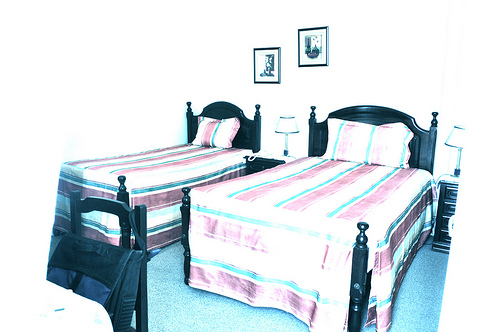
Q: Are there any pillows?
A: Yes, there is a pillow.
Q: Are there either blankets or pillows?
A: Yes, there is a pillow.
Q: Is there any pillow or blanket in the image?
A: Yes, there is a pillow.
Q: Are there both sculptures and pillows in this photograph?
A: No, there is a pillow but no sculptures.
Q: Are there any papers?
A: No, there are no papers.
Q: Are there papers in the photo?
A: No, there are no papers.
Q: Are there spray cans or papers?
A: No, there are no papers or spray cans.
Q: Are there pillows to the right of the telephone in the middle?
A: Yes, there is a pillow to the right of the phone.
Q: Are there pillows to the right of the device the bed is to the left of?
A: Yes, there is a pillow to the right of the phone.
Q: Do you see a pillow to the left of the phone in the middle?
A: No, the pillow is to the right of the telephone.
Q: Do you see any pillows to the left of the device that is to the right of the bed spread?
A: No, the pillow is to the right of the telephone.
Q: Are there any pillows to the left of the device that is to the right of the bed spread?
A: No, the pillow is to the right of the telephone.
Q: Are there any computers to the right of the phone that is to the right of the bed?
A: No, there is a pillow to the right of the phone.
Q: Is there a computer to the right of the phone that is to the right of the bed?
A: No, there is a pillow to the right of the phone.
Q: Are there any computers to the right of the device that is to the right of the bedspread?
A: No, there is a pillow to the right of the phone.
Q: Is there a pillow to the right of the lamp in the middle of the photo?
A: Yes, there is a pillow to the right of the lamp.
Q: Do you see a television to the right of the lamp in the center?
A: No, there is a pillow to the right of the lamp.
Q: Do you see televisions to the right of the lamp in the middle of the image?
A: No, there is a pillow to the right of the lamp.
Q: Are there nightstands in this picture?
A: Yes, there is a nightstand.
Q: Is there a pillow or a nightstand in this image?
A: Yes, there is a nightstand.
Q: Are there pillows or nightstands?
A: Yes, there is a nightstand.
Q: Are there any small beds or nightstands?
A: Yes, there is a small nightstand.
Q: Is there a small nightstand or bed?
A: Yes, there is a small nightstand.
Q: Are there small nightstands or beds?
A: Yes, there is a small nightstand.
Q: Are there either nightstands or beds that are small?
A: Yes, the nightstand is small.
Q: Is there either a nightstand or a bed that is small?
A: Yes, the nightstand is small.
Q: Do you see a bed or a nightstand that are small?
A: Yes, the nightstand is small.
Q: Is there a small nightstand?
A: Yes, there is a small nightstand.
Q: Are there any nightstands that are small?
A: Yes, there is a nightstand that is small.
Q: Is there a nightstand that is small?
A: Yes, there is a nightstand that is small.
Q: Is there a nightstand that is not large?
A: Yes, there is a small nightstand.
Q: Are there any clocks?
A: No, there are no clocks.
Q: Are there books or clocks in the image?
A: No, there are no clocks or books.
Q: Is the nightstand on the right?
A: Yes, the nightstand is on the right of the image.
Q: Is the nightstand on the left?
A: No, the nightstand is on the right of the image.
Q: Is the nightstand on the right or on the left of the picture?
A: The nightstand is on the right of the image.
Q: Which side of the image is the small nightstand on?
A: The nightstand is on the right of the image.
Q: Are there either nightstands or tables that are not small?
A: No, there is a nightstand but it is small.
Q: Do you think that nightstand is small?
A: Yes, the nightstand is small.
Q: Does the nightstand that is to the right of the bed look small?
A: Yes, the nightstand is small.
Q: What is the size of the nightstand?
A: The nightstand is small.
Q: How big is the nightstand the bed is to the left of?
A: The nightstand is small.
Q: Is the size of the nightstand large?
A: No, the nightstand is small.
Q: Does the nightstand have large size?
A: No, the nightstand is small.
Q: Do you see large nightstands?
A: No, there is a nightstand but it is small.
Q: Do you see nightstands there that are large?
A: No, there is a nightstand but it is small.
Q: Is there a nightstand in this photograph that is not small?
A: No, there is a nightstand but it is small.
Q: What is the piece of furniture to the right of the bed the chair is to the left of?
A: The piece of furniture is a nightstand.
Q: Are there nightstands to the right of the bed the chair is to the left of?
A: Yes, there is a nightstand to the right of the bed.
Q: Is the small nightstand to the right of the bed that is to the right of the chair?
A: Yes, the nightstand is to the right of the bed.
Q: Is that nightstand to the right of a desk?
A: No, the nightstand is to the right of the bed.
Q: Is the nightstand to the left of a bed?
A: No, the nightstand is to the right of a bed.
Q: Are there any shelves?
A: No, there are no shelves.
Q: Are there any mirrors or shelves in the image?
A: No, there are no shelves or mirrors.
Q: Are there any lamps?
A: Yes, there is a lamp.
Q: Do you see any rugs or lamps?
A: Yes, there is a lamp.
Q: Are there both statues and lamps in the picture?
A: No, there is a lamp but no statues.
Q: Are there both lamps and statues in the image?
A: No, there is a lamp but no statues.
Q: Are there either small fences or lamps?
A: Yes, there is a small lamp.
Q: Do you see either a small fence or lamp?
A: Yes, there is a small lamp.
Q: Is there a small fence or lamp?
A: Yes, there is a small lamp.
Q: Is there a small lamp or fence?
A: Yes, there is a small lamp.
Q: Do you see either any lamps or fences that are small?
A: Yes, the lamp is small.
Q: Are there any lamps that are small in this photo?
A: Yes, there is a small lamp.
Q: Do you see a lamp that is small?
A: Yes, there is a lamp that is small.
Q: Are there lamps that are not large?
A: Yes, there is a small lamp.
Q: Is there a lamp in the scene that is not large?
A: Yes, there is a small lamp.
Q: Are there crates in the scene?
A: No, there are no crates.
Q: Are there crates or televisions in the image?
A: No, there are no crates or televisions.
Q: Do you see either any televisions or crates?
A: No, there are no crates or televisions.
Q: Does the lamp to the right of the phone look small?
A: Yes, the lamp is small.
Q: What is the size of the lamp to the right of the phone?
A: The lamp is small.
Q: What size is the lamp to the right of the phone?
A: The lamp is small.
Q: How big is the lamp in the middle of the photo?
A: The lamp is small.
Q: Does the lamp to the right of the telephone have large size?
A: No, the lamp is small.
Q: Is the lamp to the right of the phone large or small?
A: The lamp is small.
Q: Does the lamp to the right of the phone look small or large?
A: The lamp is small.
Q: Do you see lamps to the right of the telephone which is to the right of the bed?
A: Yes, there is a lamp to the right of the telephone.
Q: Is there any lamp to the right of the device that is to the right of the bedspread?
A: Yes, there is a lamp to the right of the telephone.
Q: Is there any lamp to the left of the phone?
A: No, the lamp is to the right of the phone.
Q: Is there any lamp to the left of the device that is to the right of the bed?
A: No, the lamp is to the right of the phone.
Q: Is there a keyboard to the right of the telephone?
A: No, there is a lamp to the right of the telephone.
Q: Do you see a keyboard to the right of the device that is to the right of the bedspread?
A: No, there is a lamp to the right of the telephone.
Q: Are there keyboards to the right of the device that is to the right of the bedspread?
A: No, there is a lamp to the right of the telephone.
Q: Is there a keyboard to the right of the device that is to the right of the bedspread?
A: No, there is a lamp to the right of the telephone.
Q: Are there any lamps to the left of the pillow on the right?
A: Yes, there is a lamp to the left of the pillow.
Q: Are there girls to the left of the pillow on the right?
A: No, there is a lamp to the left of the pillow.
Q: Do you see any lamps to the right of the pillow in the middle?
A: Yes, there is a lamp to the right of the pillow.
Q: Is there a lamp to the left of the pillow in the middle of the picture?
A: No, the lamp is to the right of the pillow.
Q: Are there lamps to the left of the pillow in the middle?
A: No, the lamp is to the right of the pillow.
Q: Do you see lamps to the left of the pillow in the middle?
A: No, the lamp is to the right of the pillow.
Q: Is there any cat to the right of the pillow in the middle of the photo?
A: No, there is a lamp to the right of the pillow.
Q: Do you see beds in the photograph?
A: Yes, there is a bed.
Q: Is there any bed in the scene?
A: Yes, there is a bed.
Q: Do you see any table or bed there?
A: Yes, there is a bed.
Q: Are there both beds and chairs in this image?
A: Yes, there are both a bed and a chair.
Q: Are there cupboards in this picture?
A: No, there are no cupboards.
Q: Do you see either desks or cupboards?
A: No, there are no cupboards or desks.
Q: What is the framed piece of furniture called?
A: The piece of furniture is a bed.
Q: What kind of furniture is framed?
A: The furniture is a bed.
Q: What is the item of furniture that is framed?
A: The piece of furniture is a bed.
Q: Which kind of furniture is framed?
A: The furniture is a bed.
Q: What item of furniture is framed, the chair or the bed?
A: The bed is framed.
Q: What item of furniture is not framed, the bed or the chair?
A: The chair is not framed.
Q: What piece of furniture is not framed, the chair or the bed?
A: The chair is not framed.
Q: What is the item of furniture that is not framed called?
A: The piece of furniture is a chair.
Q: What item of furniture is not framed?
A: The piece of furniture is a chair.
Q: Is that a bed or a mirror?
A: That is a bed.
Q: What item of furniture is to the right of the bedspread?
A: The piece of furniture is a bed.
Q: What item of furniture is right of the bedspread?
A: The piece of furniture is a bed.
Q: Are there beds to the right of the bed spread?
A: Yes, there is a bed to the right of the bed spread.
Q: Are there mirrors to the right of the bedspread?
A: No, there is a bed to the right of the bedspread.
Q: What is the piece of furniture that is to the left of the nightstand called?
A: The piece of furniture is a bed.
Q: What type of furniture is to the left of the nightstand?
A: The piece of furniture is a bed.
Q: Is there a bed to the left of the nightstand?
A: Yes, there is a bed to the left of the nightstand.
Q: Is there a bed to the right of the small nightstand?
A: No, the bed is to the left of the nightstand.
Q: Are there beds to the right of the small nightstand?
A: No, the bed is to the left of the nightstand.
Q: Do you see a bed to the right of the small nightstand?
A: No, the bed is to the left of the nightstand.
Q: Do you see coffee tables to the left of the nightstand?
A: No, there is a bed to the left of the nightstand.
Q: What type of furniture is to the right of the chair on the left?
A: The piece of furniture is a bed.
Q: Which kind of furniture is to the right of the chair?
A: The piece of furniture is a bed.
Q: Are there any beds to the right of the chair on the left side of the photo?
A: Yes, there is a bed to the right of the chair.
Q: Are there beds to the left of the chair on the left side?
A: No, the bed is to the right of the chair.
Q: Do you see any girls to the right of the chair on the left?
A: No, there is a bed to the right of the chair.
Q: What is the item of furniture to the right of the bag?
A: The piece of furniture is a bed.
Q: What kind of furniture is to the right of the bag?
A: The piece of furniture is a bed.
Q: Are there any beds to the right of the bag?
A: Yes, there is a bed to the right of the bag.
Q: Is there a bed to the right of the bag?
A: Yes, there is a bed to the right of the bag.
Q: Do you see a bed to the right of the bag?
A: Yes, there is a bed to the right of the bag.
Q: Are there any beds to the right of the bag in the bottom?
A: Yes, there is a bed to the right of the bag.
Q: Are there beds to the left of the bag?
A: No, the bed is to the right of the bag.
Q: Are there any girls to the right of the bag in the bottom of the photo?
A: No, there is a bed to the right of the bag.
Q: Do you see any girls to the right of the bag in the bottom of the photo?
A: No, there is a bed to the right of the bag.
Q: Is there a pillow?
A: Yes, there is a pillow.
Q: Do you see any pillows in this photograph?
A: Yes, there is a pillow.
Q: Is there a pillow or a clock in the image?
A: Yes, there is a pillow.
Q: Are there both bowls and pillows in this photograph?
A: No, there is a pillow but no bowls.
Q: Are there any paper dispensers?
A: No, there are no paper dispensers.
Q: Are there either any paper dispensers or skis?
A: No, there are no paper dispensers or skis.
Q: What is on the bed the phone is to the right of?
A: The pillow is on the bed.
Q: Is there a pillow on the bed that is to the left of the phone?
A: Yes, there is a pillow on the bed.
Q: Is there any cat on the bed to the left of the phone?
A: No, there is a pillow on the bed.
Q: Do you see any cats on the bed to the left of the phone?
A: No, there is a pillow on the bed.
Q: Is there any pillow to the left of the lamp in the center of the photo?
A: Yes, there is a pillow to the left of the lamp.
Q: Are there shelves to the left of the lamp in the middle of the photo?
A: No, there is a pillow to the left of the lamp.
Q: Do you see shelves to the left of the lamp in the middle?
A: No, there is a pillow to the left of the lamp.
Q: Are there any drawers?
A: No, there are no drawers.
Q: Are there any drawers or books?
A: No, there are no drawers or books.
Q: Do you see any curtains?
A: No, there are no curtains.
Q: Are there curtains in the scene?
A: No, there are no curtains.